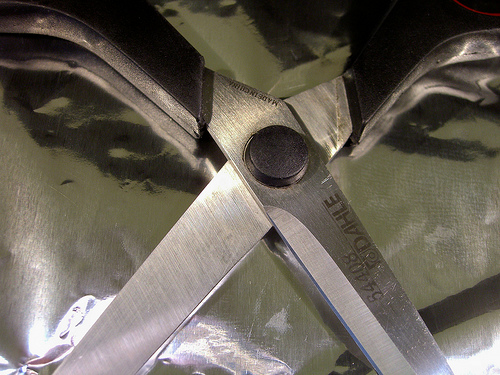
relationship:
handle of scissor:
[2, 2, 213, 128] [1, 3, 498, 373]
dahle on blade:
[322, 191, 372, 252] [297, 180, 453, 372]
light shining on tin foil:
[22, 286, 113, 353] [9, 90, 498, 330]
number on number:
[367, 290, 382, 302] [356, 281, 376, 291]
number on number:
[367, 290, 382, 302] [348, 271, 372, 282]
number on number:
[367, 290, 382, 302] [345, 263, 366, 271]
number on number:
[367, 290, 382, 302] [334, 251, 356, 262]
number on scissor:
[367, 290, 382, 302] [1, 3, 498, 373]